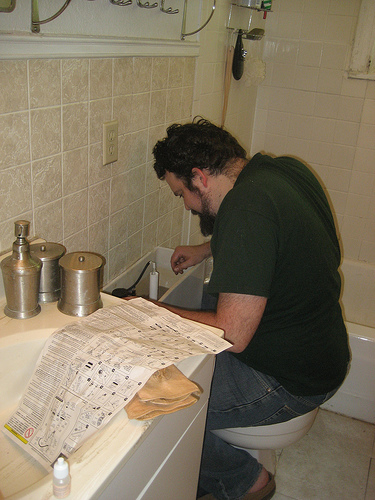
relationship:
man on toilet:
[154, 104, 276, 298] [125, 264, 308, 491]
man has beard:
[154, 104, 276, 298] [179, 192, 217, 244]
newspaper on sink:
[27, 332, 198, 431] [6, 323, 147, 499]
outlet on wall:
[99, 117, 130, 166] [56, 68, 134, 187]